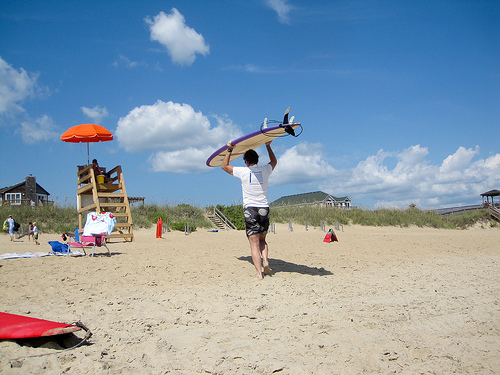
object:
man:
[220, 135, 278, 282]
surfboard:
[203, 107, 303, 168]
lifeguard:
[84, 158, 115, 185]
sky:
[1, 2, 499, 205]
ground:
[1, 222, 496, 375]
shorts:
[242, 206, 271, 237]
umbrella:
[58, 122, 115, 167]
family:
[3, 213, 41, 246]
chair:
[65, 211, 116, 260]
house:
[1, 173, 56, 209]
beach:
[1, 208, 498, 374]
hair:
[243, 148, 259, 165]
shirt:
[232, 163, 275, 210]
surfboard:
[0, 310, 92, 352]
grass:
[1, 202, 495, 234]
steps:
[217, 227, 227, 229]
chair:
[74, 157, 138, 243]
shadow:
[234, 252, 334, 278]